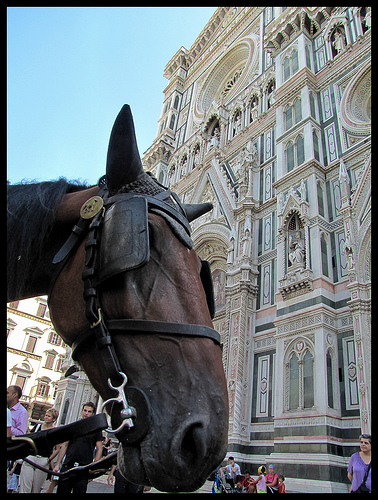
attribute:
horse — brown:
[4, 97, 247, 493]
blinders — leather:
[86, 192, 153, 294]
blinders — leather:
[196, 255, 223, 322]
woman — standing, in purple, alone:
[339, 431, 377, 495]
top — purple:
[344, 451, 373, 493]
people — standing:
[52, 395, 108, 494]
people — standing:
[20, 404, 62, 495]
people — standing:
[6, 381, 35, 496]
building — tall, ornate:
[45, 8, 370, 495]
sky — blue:
[8, 8, 219, 195]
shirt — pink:
[4, 398, 31, 447]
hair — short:
[358, 433, 371, 447]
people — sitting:
[273, 474, 287, 494]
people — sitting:
[266, 462, 280, 495]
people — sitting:
[247, 462, 268, 497]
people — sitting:
[237, 468, 253, 495]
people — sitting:
[216, 452, 245, 496]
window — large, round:
[183, 36, 263, 116]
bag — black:
[351, 459, 372, 496]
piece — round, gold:
[77, 195, 107, 223]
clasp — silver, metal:
[95, 369, 141, 436]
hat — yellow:
[255, 464, 266, 476]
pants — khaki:
[15, 450, 53, 499]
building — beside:
[2, 287, 75, 424]